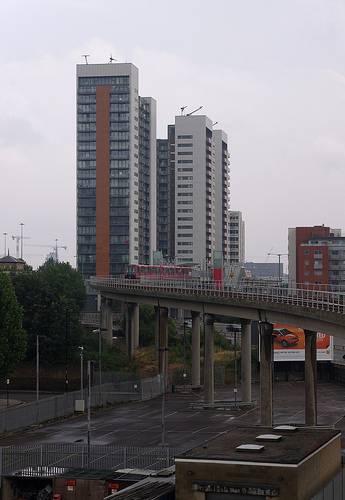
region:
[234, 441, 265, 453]
rectangular opaque skylight in roof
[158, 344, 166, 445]
tall metal light pole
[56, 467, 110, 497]
metal trash dumpster with lid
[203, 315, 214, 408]
raised track support column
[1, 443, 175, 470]
long metal fence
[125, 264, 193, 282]
red passenger train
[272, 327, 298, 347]
picture of auto on sign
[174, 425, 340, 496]
brown industrial building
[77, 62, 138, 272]
tall multi story building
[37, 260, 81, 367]
tall and lush green tree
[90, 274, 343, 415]
section of elevated railway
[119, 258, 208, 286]
red train on the railway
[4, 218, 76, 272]
construction cranes in the distance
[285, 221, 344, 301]
apartment buildings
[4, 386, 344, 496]
low building with an empty parking lot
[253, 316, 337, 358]
billboard with a car on it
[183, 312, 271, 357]
parking lot with cars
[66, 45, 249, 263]
series of skyscrapers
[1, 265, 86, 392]
trees along the road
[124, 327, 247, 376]
undeveloped land below the railway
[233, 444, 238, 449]
roof of a building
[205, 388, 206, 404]
edge of a pillar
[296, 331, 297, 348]
edge of a road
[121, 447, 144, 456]
part of a fence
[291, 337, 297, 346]
part of a board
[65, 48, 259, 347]
large towering skyscrapers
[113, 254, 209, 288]
red commuter train on tracks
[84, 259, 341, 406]
commuter train on overhead tracks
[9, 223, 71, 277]
tall crane building new buildings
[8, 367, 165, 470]
fence around the parking lot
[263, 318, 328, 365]
orange billboard advertising car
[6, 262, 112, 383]
large trees beside train tracks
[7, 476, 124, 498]
tunnel under the parking lot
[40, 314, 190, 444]
streetlamps in parking lot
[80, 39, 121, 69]
antenna on top of building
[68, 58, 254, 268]
Buildings are in the background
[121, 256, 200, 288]
A train is in the background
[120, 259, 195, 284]
The train is red in color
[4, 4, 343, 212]
The sky is cloudy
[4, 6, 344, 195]
The sky is gray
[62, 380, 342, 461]
A parking lot is in view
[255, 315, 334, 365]
A billard in the background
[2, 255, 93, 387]
Trees are in the background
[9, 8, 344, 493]
Photo was taken in the daytime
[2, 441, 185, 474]
A fence is in the foreground